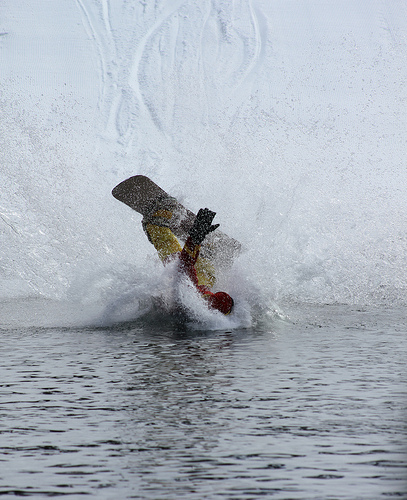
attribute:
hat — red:
[213, 293, 232, 305]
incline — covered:
[37, 17, 337, 172]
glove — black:
[186, 203, 223, 246]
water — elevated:
[55, 5, 381, 170]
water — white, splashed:
[3, 119, 405, 498]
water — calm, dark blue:
[0, 292, 405, 498]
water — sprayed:
[22, 153, 392, 345]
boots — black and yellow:
[142, 198, 180, 232]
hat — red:
[210, 290, 234, 315]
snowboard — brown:
[94, 181, 253, 262]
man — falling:
[137, 191, 238, 317]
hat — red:
[206, 290, 236, 316]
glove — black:
[181, 205, 217, 243]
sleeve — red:
[176, 237, 201, 304]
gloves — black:
[184, 203, 227, 242]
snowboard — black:
[90, 153, 274, 263]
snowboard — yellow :
[109, 156, 255, 244]